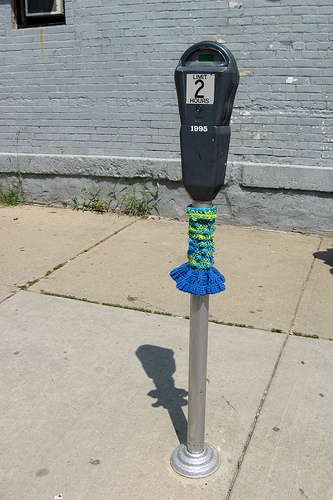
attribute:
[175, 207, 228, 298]
scarf — knit, crocheted, knitted, blue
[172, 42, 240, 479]
meter — metal, limited, black, silver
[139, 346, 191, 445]
shadow — cast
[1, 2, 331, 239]
building — brick, gray, damaged, blue, peeling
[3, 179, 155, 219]
weeds — growing, small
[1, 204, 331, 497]
pavement — spotted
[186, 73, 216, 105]
sign — white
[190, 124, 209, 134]
number — white